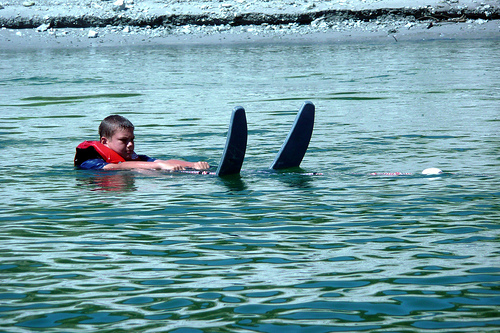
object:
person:
[74, 115, 177, 175]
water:
[220, 214, 291, 248]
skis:
[212, 104, 250, 179]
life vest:
[75, 140, 126, 163]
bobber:
[420, 164, 447, 181]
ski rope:
[281, 171, 417, 176]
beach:
[0, 2, 500, 40]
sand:
[64, 33, 98, 49]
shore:
[245, 36, 287, 57]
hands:
[150, 157, 205, 175]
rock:
[286, 23, 308, 36]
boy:
[75, 116, 144, 172]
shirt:
[129, 158, 137, 162]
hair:
[102, 115, 122, 131]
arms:
[88, 158, 186, 173]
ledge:
[166, 0, 228, 30]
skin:
[108, 141, 120, 149]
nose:
[125, 141, 132, 147]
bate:
[151, 154, 186, 172]